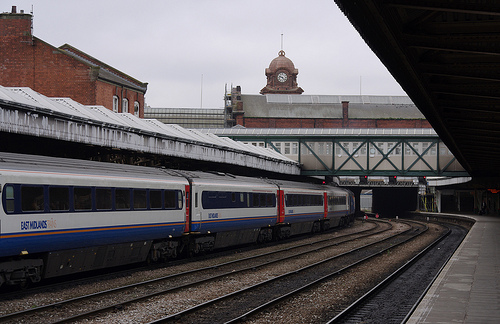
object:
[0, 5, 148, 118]
brick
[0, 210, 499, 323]
ground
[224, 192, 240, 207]
window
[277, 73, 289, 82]
clock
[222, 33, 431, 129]
building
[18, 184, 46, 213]
window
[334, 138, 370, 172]
window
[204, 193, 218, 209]
window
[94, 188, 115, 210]
window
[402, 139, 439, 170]
window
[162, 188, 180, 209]
window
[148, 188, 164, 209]
window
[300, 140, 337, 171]
window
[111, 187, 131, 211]
square window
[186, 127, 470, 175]
bridge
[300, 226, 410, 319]
tracks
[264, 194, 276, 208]
window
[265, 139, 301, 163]
window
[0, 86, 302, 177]
roof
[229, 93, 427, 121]
roof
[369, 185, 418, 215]
tunnel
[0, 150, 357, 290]
train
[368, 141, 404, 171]
window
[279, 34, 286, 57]
metal pole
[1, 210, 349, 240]
stripe